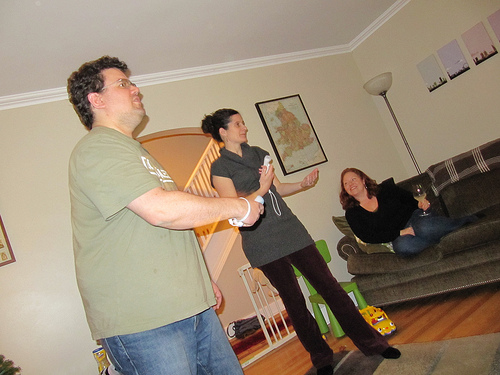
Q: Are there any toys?
A: Yes, there is a toy.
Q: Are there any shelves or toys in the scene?
A: Yes, there is a toy.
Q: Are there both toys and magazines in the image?
A: No, there is a toy but no magazines.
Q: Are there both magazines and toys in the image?
A: No, there is a toy but no magazines.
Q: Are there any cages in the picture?
A: No, there are no cages.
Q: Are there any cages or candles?
A: No, there are no cages or candles.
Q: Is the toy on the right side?
A: Yes, the toy is on the right of the image.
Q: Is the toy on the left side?
A: No, the toy is on the right of the image.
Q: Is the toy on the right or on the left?
A: The toy is on the right of the image.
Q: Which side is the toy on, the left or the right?
A: The toy is on the right of the image.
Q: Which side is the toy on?
A: The toy is on the right of the image.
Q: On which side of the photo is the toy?
A: The toy is on the right of the image.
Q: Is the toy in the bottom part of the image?
A: Yes, the toy is in the bottom of the image.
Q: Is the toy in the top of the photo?
A: No, the toy is in the bottom of the image.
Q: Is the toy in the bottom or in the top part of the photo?
A: The toy is in the bottom of the image.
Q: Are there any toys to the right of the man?
A: Yes, there is a toy to the right of the man.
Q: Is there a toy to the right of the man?
A: Yes, there is a toy to the right of the man.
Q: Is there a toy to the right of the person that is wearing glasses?
A: Yes, there is a toy to the right of the man.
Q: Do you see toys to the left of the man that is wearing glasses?
A: No, the toy is to the right of the man.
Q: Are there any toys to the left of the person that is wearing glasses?
A: No, the toy is to the right of the man.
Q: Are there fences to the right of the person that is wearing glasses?
A: No, there is a toy to the right of the man.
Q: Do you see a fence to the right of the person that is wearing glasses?
A: No, there is a toy to the right of the man.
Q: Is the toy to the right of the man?
A: Yes, the toy is to the right of the man.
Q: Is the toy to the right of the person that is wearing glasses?
A: Yes, the toy is to the right of the man.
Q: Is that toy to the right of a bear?
A: No, the toy is to the right of the man.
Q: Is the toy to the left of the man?
A: No, the toy is to the right of the man.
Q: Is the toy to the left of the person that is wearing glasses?
A: No, the toy is to the right of the man.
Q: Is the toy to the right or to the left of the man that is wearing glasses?
A: The toy is to the right of the man.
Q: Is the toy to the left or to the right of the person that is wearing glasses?
A: The toy is to the right of the man.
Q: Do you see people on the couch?
A: Yes, there is a person on the couch.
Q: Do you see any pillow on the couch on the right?
A: No, there is a person on the couch.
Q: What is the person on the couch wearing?
A: The person is wearing a shirt.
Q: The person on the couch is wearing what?
A: The person is wearing a shirt.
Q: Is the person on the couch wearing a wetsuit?
A: No, the person is wearing a shirt.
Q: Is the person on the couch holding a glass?
A: Yes, the person is holding a glass.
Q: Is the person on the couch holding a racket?
A: No, the person is holding a glass.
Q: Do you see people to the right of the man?
A: Yes, there is a person to the right of the man.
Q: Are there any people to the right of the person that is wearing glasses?
A: Yes, there is a person to the right of the man.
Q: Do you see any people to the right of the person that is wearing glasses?
A: Yes, there is a person to the right of the man.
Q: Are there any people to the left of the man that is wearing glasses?
A: No, the person is to the right of the man.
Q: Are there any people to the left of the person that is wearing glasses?
A: No, the person is to the right of the man.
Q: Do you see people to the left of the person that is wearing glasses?
A: No, the person is to the right of the man.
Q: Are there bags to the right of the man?
A: No, there is a person to the right of the man.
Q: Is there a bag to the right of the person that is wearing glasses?
A: No, there is a person to the right of the man.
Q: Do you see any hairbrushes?
A: No, there are no hairbrushes.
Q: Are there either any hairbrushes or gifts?
A: No, there are no hairbrushes or gifts.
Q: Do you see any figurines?
A: No, there are no figurines.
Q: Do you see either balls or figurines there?
A: No, there are no figurines or balls.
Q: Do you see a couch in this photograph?
A: Yes, there is a couch.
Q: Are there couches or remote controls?
A: Yes, there is a couch.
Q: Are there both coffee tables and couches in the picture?
A: No, there is a couch but no coffee tables.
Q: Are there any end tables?
A: No, there are no end tables.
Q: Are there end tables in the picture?
A: No, there are no end tables.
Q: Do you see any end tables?
A: No, there are no end tables.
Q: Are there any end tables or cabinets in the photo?
A: No, there are no end tables or cabinets.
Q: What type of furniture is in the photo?
A: The furniture is a couch.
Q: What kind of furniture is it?
A: The piece of furniture is a couch.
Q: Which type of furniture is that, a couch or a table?
A: This is a couch.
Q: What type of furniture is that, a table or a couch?
A: This is a couch.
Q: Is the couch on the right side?
A: Yes, the couch is on the right of the image.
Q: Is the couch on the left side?
A: No, the couch is on the right of the image.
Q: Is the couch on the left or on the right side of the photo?
A: The couch is on the right of the image.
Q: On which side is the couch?
A: The couch is on the right of the image.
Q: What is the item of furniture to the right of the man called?
A: The piece of furniture is a couch.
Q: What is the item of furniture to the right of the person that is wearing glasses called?
A: The piece of furniture is a couch.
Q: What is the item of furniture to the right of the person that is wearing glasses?
A: The piece of furniture is a couch.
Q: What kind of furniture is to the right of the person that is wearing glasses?
A: The piece of furniture is a couch.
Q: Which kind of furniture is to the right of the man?
A: The piece of furniture is a couch.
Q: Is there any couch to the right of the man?
A: Yes, there is a couch to the right of the man.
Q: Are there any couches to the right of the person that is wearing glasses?
A: Yes, there is a couch to the right of the man.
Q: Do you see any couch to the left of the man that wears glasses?
A: No, the couch is to the right of the man.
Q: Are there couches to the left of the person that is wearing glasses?
A: No, the couch is to the right of the man.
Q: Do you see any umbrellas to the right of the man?
A: No, there is a couch to the right of the man.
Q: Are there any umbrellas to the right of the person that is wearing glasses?
A: No, there is a couch to the right of the man.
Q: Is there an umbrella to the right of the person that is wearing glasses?
A: No, there is a couch to the right of the man.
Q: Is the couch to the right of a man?
A: Yes, the couch is to the right of a man.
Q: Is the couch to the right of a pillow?
A: No, the couch is to the right of a man.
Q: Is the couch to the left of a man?
A: No, the couch is to the right of a man.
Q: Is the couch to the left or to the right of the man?
A: The couch is to the right of the man.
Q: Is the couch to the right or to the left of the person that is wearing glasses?
A: The couch is to the right of the man.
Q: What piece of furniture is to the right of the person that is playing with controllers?
A: The piece of furniture is a couch.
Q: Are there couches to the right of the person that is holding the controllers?
A: Yes, there is a couch to the right of the person.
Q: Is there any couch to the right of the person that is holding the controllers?
A: Yes, there is a couch to the right of the person.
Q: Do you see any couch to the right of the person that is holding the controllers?
A: Yes, there is a couch to the right of the person.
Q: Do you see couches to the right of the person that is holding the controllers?
A: Yes, there is a couch to the right of the person.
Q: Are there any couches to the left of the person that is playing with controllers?
A: No, the couch is to the right of the person.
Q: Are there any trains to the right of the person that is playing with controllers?
A: No, there is a couch to the right of the person.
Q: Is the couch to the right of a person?
A: Yes, the couch is to the right of a person.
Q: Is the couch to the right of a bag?
A: No, the couch is to the right of a person.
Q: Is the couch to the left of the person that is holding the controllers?
A: No, the couch is to the right of the person.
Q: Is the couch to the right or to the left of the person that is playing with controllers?
A: The couch is to the right of the person.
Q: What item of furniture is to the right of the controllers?
A: The piece of furniture is a couch.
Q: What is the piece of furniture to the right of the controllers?
A: The piece of furniture is a couch.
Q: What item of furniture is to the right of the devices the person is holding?
A: The piece of furniture is a couch.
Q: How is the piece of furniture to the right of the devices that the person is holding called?
A: The piece of furniture is a couch.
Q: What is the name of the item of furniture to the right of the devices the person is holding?
A: The piece of furniture is a couch.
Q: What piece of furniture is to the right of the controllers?
A: The piece of furniture is a couch.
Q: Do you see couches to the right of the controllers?
A: Yes, there is a couch to the right of the controllers.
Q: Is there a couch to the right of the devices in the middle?
A: Yes, there is a couch to the right of the controllers.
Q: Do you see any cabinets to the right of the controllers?
A: No, there is a couch to the right of the controllers.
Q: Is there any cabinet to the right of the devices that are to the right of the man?
A: No, there is a couch to the right of the controllers.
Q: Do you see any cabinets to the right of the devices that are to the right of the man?
A: No, there is a couch to the right of the controllers.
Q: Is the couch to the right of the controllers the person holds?
A: Yes, the couch is to the right of the controllers.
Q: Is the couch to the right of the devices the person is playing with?
A: Yes, the couch is to the right of the controllers.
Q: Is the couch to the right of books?
A: No, the couch is to the right of the controllers.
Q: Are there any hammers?
A: No, there are no hammers.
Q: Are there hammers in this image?
A: No, there are no hammers.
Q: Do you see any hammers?
A: No, there are no hammers.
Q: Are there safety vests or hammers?
A: No, there are no hammers or safety vests.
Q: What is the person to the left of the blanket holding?
A: The person is holding the controllers.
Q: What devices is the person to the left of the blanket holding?
A: The person is holding the controllers.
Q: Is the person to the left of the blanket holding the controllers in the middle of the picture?
A: Yes, the person is holding the controllers.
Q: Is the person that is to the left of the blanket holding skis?
A: No, the person is holding the controllers.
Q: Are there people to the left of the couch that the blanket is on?
A: Yes, there is a person to the left of the couch.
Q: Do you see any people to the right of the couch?
A: No, the person is to the left of the couch.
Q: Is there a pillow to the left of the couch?
A: No, there is a person to the left of the couch.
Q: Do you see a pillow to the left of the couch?
A: No, there is a person to the left of the couch.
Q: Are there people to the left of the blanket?
A: Yes, there is a person to the left of the blanket.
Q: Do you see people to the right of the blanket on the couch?
A: No, the person is to the left of the blanket.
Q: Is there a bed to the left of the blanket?
A: No, there is a person to the left of the blanket.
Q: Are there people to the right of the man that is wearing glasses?
A: Yes, there is a person to the right of the man.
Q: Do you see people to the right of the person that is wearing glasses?
A: Yes, there is a person to the right of the man.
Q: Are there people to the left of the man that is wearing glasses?
A: No, the person is to the right of the man.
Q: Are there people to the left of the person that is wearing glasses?
A: No, the person is to the right of the man.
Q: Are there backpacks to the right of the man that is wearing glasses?
A: No, there is a person to the right of the man.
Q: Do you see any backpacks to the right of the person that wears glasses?
A: No, there is a person to the right of the man.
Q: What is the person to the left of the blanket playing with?
A: The person is playing with controllers.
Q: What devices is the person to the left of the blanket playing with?
A: The person is playing with controllers.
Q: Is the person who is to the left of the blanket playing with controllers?
A: Yes, the person is playing with controllers.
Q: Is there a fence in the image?
A: No, there are no fences.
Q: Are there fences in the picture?
A: No, there are no fences.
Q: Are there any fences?
A: No, there are no fences.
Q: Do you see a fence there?
A: No, there are no fences.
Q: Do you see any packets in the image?
A: No, there are no packets.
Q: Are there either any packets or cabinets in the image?
A: No, there are no packets or cabinets.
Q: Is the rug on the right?
A: Yes, the rug is on the right of the image.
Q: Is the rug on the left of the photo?
A: No, the rug is on the right of the image.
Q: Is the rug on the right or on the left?
A: The rug is on the right of the image.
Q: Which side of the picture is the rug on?
A: The rug is on the right of the image.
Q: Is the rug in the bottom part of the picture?
A: Yes, the rug is in the bottom of the image.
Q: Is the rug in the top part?
A: No, the rug is in the bottom of the image.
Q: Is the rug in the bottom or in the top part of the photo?
A: The rug is in the bottom of the image.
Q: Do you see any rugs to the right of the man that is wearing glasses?
A: Yes, there is a rug to the right of the man.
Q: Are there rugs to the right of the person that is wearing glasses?
A: Yes, there is a rug to the right of the man.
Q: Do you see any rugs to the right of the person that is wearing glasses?
A: Yes, there is a rug to the right of the man.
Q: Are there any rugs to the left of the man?
A: No, the rug is to the right of the man.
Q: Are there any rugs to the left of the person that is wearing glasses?
A: No, the rug is to the right of the man.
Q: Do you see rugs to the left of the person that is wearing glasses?
A: No, the rug is to the right of the man.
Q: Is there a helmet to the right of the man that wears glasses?
A: No, there is a rug to the right of the man.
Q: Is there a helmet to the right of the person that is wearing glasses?
A: No, there is a rug to the right of the man.